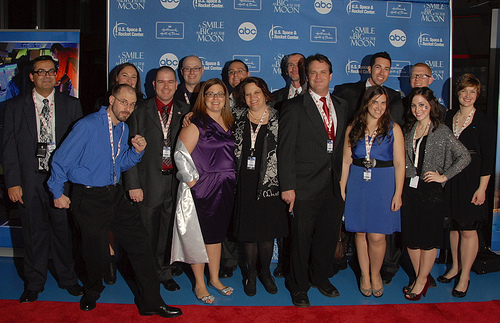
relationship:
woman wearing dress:
[338, 86, 404, 297] [345, 120, 404, 236]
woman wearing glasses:
[176, 77, 235, 304] [203, 89, 226, 101]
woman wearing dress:
[444, 73, 493, 303] [445, 106, 494, 232]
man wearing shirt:
[44, 84, 186, 318] [44, 106, 150, 198]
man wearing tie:
[2, 54, 89, 304] [34, 95, 54, 171]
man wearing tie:
[277, 53, 348, 307] [319, 97, 332, 122]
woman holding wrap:
[176, 77, 235, 304] [168, 135, 211, 271]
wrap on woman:
[168, 135, 211, 271] [176, 77, 235, 304]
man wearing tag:
[44, 84, 186, 318] [110, 173, 119, 186]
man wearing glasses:
[44, 84, 186, 318] [112, 98, 137, 110]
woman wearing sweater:
[399, 86, 474, 304] [396, 119, 472, 187]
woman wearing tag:
[338, 86, 404, 297] [362, 170, 373, 183]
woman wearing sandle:
[338, 86, 404, 297] [358, 273, 373, 297]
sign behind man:
[2, 28, 81, 260] [2, 54, 89, 304]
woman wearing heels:
[399, 86, 474, 304] [405, 269, 430, 302]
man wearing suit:
[2, 54, 89, 304] [4, 88, 84, 293]